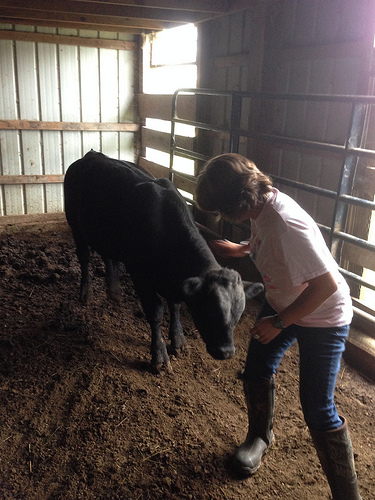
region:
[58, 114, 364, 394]
a lady petting the cow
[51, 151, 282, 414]
a young cow in the barn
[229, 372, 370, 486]
a lady wearing boots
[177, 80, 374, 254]
a metal cattle guard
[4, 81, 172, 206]
wooden slats attached to the wall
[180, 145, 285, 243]
the lady has short brown hair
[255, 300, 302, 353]
the lady is wearing a wrist watch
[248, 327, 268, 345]
the lady is wearing a wedding ring on her finger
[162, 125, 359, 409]
the lady is petting the cow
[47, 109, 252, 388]
a black cow in a pen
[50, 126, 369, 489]
a woman in front a cow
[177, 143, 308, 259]
the woman is blonde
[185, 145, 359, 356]
woman wears a white shirt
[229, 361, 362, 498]
a pair of black boots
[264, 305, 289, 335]
a clock on the wrist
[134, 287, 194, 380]
front legs of cow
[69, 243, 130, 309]
back legs of cow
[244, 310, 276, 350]
a ring on a finger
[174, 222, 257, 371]
hand above the head of cow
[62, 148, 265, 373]
a large black cow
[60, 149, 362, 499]
a lady about to pet a cow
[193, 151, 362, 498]
a lady wearing brown boots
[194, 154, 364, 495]
a woman wearing blue jeans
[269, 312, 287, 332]
a watch on a wrist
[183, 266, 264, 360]
head of a black cow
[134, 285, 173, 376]
front right leg of black cow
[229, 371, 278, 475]
right boot used for farm duties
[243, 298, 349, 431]
a pair of blue jeans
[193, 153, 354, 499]
lady with short brown hair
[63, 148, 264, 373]
Black cow standing in the dirt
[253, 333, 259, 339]
Ring on woman's finger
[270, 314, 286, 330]
Watch on woman's wrist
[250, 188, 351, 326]
Woman's white sleeveless shirt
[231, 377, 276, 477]
Tall brown boot on woman's foot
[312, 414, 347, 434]
Gap on top of woman's boot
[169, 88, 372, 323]
Metal bars on wall behind woman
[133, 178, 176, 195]
Hump on back of cow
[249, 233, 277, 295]
Design on front of woman's shirt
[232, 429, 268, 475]
Sunlight shining on front of woman's boot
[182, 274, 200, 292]
the black ear of the cow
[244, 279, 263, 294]
the black ear of the cow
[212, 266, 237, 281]
the tuft of hair on the cow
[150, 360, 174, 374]
the hoof of the cow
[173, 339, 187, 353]
the hoof of the cow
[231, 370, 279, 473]
the brown tall rubber boot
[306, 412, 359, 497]
the brown tall rubber boot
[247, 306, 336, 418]
the pair of blue jeans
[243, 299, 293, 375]
the leg of the woman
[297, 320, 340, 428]
the leg of the woman